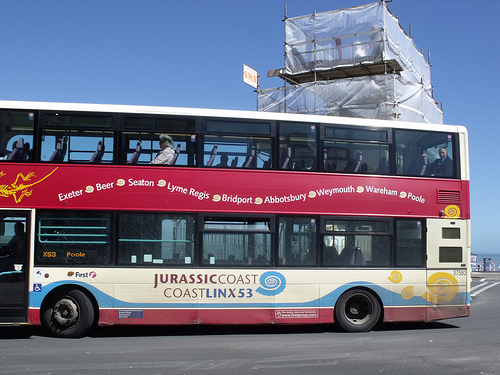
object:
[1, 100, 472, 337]
bus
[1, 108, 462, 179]
passengers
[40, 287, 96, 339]
wheel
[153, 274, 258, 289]
words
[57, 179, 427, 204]
words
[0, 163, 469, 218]
red portion of bus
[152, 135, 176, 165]
woman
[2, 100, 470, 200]
upper level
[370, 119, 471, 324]
back of bus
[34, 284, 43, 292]
handicap sign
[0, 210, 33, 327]
bus door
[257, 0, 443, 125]
structure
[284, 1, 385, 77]
in plastic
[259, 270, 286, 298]
swirl design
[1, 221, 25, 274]
driver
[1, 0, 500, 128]
day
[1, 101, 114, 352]
front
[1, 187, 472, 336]
first level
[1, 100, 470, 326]
side of bus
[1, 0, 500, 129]
sky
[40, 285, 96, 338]
tires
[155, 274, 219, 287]
jurassic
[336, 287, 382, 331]
tire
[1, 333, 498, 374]
ground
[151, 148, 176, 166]
shirt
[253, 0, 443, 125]
plastic walls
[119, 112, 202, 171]
upper window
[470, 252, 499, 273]
glimps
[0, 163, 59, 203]
animal skeleton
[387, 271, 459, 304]
abstract shells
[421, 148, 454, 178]
man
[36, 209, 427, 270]
windows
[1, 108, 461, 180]
windows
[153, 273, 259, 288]
jurassiccoast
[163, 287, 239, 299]
words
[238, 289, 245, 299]
number